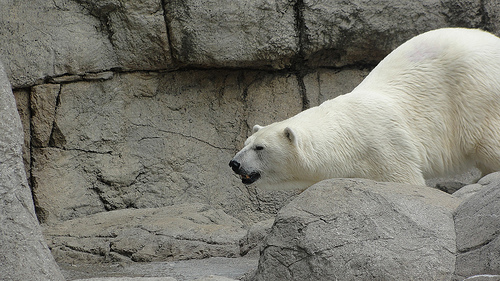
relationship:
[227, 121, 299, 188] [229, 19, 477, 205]
head of a bear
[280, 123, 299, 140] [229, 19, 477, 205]
ear of a bear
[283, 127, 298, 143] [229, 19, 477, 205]
ear of a bear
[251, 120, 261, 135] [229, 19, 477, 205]
ear of a bear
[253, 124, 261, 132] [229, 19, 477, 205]
ear of a bear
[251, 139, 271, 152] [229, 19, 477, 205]
eye of a bear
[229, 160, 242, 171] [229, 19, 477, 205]
nose of a bear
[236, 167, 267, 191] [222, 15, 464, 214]
mouth of a bear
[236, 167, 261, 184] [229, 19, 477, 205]
mouth of a bear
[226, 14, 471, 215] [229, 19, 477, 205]
body of a bear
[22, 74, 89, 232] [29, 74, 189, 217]
cracks in rock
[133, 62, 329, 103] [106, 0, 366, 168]
shadow of rock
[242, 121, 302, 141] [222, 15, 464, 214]
two ears of bear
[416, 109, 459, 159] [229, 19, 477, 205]
fur of a bear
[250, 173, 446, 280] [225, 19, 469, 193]
rock in front of a bear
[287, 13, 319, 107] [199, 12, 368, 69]
line of a rock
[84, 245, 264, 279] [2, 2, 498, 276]
floor of bear pen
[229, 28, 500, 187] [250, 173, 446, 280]
bear near a rock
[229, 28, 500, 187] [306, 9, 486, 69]
bear near a rock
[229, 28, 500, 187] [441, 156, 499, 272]
bear near a rock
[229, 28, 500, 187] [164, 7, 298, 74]
bear near a rock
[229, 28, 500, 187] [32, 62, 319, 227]
bear near a rock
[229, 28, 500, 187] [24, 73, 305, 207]
bear near a rock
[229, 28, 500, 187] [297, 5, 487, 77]
bear near a rock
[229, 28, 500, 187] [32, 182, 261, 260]
bear near a rock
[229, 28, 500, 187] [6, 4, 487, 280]
bear in a zoo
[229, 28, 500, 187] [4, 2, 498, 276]
bear among rocks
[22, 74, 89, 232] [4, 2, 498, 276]
cracks in rocks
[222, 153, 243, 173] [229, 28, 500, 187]
nose on bear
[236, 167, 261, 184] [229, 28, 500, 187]
mouth on bear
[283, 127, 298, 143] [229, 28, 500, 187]
ear of a bear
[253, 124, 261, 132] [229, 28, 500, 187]
ear of a bear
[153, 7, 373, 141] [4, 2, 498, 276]
lines in rocks